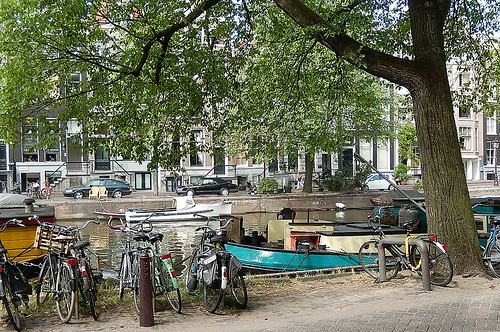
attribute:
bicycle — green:
[147, 221, 182, 310]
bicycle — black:
[352, 223, 455, 292]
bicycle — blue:
[471, 217, 499, 281]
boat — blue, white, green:
[223, 235, 358, 272]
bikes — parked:
[28, 208, 259, 329]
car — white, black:
[362, 165, 399, 193]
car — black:
[170, 177, 240, 197]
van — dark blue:
[64, 175, 133, 200]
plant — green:
[257, 176, 283, 201]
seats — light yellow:
[85, 186, 111, 201]